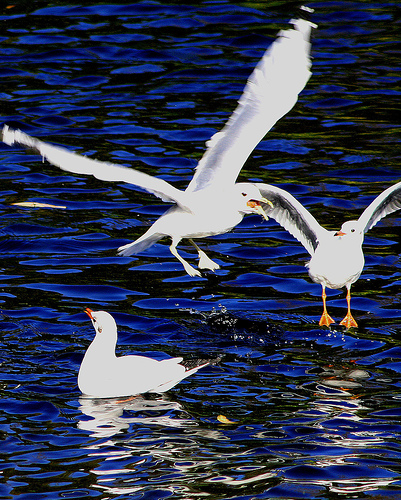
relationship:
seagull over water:
[33, 286, 226, 422] [199, 286, 261, 337]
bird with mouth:
[113, 27, 315, 257] [243, 191, 275, 219]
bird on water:
[113, 27, 315, 257] [199, 286, 261, 337]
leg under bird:
[144, 236, 224, 295] [113, 27, 315, 257]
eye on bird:
[239, 178, 262, 203] [113, 27, 315, 257]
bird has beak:
[113, 27, 315, 257] [319, 218, 360, 246]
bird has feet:
[113, 27, 315, 257] [305, 286, 378, 331]